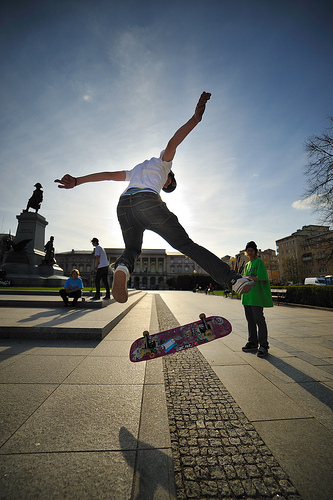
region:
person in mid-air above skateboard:
[49, 88, 252, 302]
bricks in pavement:
[151, 287, 296, 493]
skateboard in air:
[124, 306, 229, 359]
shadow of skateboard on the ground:
[114, 420, 180, 494]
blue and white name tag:
[158, 334, 172, 347]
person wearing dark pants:
[236, 302, 269, 340]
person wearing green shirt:
[238, 256, 267, 302]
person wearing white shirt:
[122, 149, 172, 194]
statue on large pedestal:
[7, 181, 68, 286]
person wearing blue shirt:
[62, 274, 85, 291]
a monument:
[1, 179, 64, 292]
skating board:
[127, 314, 233, 362]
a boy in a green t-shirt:
[240, 239, 276, 357]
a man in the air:
[55, 92, 250, 300]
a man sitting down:
[54, 268, 89, 305]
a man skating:
[61, 70, 285, 361]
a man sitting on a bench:
[184, 280, 223, 299]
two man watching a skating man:
[56, 242, 302, 354]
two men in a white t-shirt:
[88, 85, 254, 303]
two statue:
[22, 180, 57, 266]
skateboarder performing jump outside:
[52, 125, 313, 424]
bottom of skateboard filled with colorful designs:
[115, 311, 232, 366]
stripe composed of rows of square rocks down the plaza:
[144, 284, 287, 481]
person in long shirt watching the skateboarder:
[228, 231, 288, 356]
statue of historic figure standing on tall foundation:
[9, 175, 55, 262]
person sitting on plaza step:
[52, 233, 111, 315]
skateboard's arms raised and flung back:
[47, 85, 257, 211]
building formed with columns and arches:
[65, 228, 174, 289]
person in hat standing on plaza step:
[82, 224, 109, 304]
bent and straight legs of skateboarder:
[104, 205, 248, 316]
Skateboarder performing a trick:
[26, 90, 257, 364]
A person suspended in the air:
[46, 90, 256, 304]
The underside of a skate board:
[130, 312, 232, 366]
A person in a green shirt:
[236, 239, 275, 360]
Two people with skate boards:
[56, 232, 110, 312]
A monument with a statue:
[10, 174, 43, 260]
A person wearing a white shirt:
[87, 234, 107, 272]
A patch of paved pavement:
[74, 375, 292, 468]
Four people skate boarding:
[41, 87, 276, 363]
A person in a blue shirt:
[56, 269, 87, 303]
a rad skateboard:
[124, 307, 234, 369]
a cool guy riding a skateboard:
[64, 85, 244, 298]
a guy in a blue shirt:
[55, 260, 81, 306]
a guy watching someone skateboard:
[236, 233, 273, 355]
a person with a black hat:
[87, 232, 107, 299]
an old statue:
[3, 175, 59, 284]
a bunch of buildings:
[273, 220, 327, 280]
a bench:
[267, 283, 285, 300]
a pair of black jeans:
[237, 302, 273, 340]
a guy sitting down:
[54, 264, 83, 307]